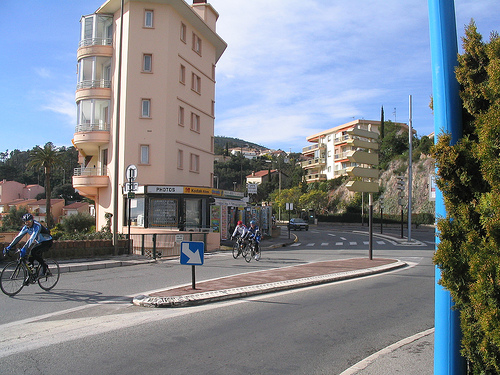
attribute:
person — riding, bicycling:
[2, 210, 53, 278]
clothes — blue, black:
[247, 225, 259, 244]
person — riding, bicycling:
[232, 220, 249, 240]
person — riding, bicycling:
[243, 220, 264, 250]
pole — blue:
[429, 0, 480, 372]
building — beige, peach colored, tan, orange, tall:
[71, 2, 233, 253]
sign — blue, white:
[180, 242, 205, 265]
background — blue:
[180, 246, 201, 262]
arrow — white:
[183, 244, 203, 263]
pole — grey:
[403, 94, 414, 240]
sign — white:
[149, 187, 184, 191]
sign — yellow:
[184, 183, 215, 198]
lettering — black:
[155, 186, 177, 191]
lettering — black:
[188, 186, 212, 196]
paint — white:
[4, 223, 411, 357]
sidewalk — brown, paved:
[135, 247, 405, 314]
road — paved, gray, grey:
[4, 215, 437, 365]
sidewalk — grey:
[354, 326, 432, 373]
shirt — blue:
[8, 220, 58, 254]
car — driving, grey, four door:
[285, 214, 310, 230]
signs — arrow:
[178, 241, 204, 264]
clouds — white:
[212, 0, 418, 137]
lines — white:
[3, 209, 433, 356]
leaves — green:
[5, 119, 429, 232]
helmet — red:
[237, 217, 244, 226]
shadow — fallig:
[28, 253, 308, 311]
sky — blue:
[4, 4, 494, 161]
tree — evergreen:
[427, 16, 498, 371]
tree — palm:
[24, 142, 75, 233]